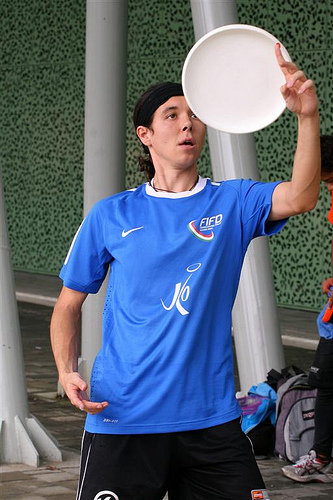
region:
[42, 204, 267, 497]
the shirt is blue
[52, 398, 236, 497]
the shorts are black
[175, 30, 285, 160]
the frisbee is white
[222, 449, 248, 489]
part of a short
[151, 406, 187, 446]
edge of a top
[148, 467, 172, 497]
part of a short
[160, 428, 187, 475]
edge of a short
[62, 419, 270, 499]
THE MAN IS WEARING SHORTS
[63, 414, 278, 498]
THE MAN'S SHORTS ARE BLACK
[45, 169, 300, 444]
THE MAN IS WEARING A T-SHIRT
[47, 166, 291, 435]
THE MAN'S T-SHIRT IS BLUE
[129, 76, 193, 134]
THE MAN IS WEARING A HEAD BAND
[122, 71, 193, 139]
THE MAN'S HEAD BAND IS BLACK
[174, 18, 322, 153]
THE MAN IS HOLDING A FRISBEE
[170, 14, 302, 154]
THE FRISBEE THE MAN IS HOLDING IS WHITE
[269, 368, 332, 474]
THE BACKPACK IS ON THE GROUND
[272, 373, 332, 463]
THE BACKPACK IS GREY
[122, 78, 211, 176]
the head of a man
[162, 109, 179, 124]
the eye of a man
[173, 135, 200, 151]
the mouth of a man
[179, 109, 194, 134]
the nose of a man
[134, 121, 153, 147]
the ear of a man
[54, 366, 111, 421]
the hand of a man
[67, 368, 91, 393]
the thumb of a man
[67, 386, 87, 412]
the finger of a man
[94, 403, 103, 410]
the finger nail of a man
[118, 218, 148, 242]
a logo on the shirt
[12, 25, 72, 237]
The wall is the color green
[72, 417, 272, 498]
The shorts on the boy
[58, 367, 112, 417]
The hand on the boy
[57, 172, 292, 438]
The shirt on the boy is the color blue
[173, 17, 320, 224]
The boy has a white frisbee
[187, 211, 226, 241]
The logo on the shirt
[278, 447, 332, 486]
The shoe on the person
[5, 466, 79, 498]
The ground is made of concrete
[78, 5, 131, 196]
The pole is the color gray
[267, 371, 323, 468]
A backpack sitting on the ground